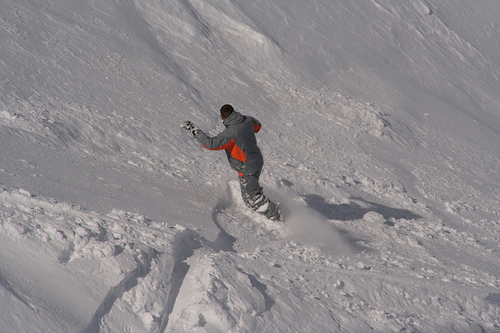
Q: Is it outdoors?
A: Yes, it is outdoors.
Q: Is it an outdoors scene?
A: Yes, it is outdoors.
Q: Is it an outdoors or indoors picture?
A: It is outdoors.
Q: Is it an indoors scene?
A: No, it is outdoors.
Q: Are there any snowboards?
A: Yes, there is a snowboard.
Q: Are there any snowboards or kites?
A: Yes, there is a snowboard.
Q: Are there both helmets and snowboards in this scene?
A: No, there is a snowboard but no helmets.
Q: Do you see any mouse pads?
A: No, there are no mouse pads.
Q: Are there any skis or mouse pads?
A: No, there are no mouse pads or skis.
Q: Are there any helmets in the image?
A: No, there are no helmets.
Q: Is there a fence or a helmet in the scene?
A: No, there are no helmets or fences.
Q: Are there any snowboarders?
A: Yes, there is a snowboarder.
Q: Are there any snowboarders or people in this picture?
A: Yes, there is a snowboarder.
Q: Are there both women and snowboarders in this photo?
A: No, there is a snowboarder but no women.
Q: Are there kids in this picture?
A: No, there are no kids.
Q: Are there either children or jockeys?
A: No, there are no children or jockeys.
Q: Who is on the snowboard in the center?
A: The snowboarder is on the snowboard.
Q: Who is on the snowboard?
A: The snowboarder is on the snowboard.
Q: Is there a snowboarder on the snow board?
A: Yes, there is a snowboarder on the snow board.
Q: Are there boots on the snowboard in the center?
A: No, there is a snowboarder on the snow board.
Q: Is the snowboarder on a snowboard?
A: Yes, the snowboarder is on a snowboard.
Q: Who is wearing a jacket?
A: The snowboarder is wearing a jacket.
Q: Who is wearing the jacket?
A: The snowboarder is wearing a jacket.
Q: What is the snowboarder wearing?
A: The snowboarder is wearing a jacket.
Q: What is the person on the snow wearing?
A: The snowboarder is wearing a jacket.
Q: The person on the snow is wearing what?
A: The snowboarder is wearing a jacket.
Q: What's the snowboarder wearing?
A: The snowboarder is wearing a jacket.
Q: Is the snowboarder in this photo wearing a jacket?
A: Yes, the snowboarder is wearing a jacket.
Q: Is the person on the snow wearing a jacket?
A: Yes, the snowboarder is wearing a jacket.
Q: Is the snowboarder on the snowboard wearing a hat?
A: No, the snowboarder is wearing a jacket.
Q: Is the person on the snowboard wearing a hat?
A: No, the snowboarder is wearing a jacket.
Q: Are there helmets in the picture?
A: No, there are no helmets.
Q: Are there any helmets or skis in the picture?
A: No, there are no helmets or skis.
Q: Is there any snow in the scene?
A: Yes, there is snow.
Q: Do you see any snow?
A: Yes, there is snow.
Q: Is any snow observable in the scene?
A: Yes, there is snow.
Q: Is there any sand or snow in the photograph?
A: Yes, there is snow.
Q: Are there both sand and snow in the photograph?
A: No, there is snow but no sand.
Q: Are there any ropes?
A: No, there are no ropes.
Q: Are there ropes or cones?
A: No, there are no ropes or cones.